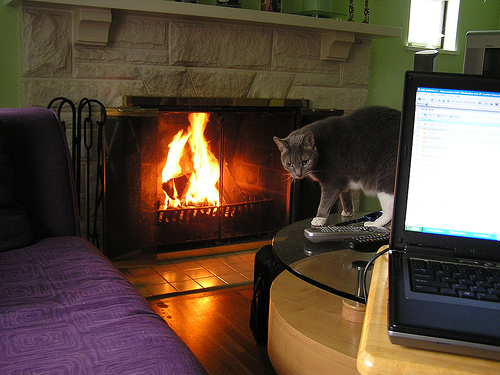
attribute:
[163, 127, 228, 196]
fire — orange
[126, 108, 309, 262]
fireplace — beige, stone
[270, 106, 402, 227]
cat — gray, white, grey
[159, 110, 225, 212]
fire — bright orange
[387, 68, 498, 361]
laptop — black, silver, grey, open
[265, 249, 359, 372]
table top — round, wood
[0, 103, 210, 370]
couch — purple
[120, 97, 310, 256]
fireplace — stone wall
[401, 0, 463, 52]
window — small, bright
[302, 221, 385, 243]
remote control — silver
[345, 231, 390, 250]
remote control — black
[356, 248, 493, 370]
table top — light, wood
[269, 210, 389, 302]
table — glass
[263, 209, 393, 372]
coffee table — glass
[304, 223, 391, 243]
remote control — silver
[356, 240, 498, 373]
tv table — light, wood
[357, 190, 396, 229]
leg — white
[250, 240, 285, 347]
suitcase — black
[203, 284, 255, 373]
floor — brown, hardwood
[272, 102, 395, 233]
cat — grey, white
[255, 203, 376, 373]
coffee table — wooden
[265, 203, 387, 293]
top — glass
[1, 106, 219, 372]
sofa — purple, deep purple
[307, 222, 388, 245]
remote controller — silver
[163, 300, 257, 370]
floors — hardwood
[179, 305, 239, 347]
floor — hard wood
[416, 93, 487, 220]
browser window — open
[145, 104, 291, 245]
fireplace — wood burning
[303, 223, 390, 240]
remote control — gray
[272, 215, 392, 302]
table top — glass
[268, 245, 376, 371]
base — wooden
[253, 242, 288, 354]
suitcase — black